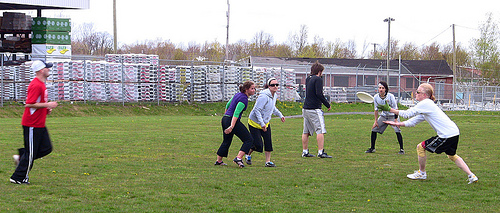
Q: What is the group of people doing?
A: Frisbee.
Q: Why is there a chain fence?
A: To separate the field and building.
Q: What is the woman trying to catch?
A: Frisbee.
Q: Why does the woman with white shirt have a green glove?
A: Protection for hand.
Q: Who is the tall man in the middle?
A: Player.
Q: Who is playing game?
A: Young woman.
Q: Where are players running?
A: Field.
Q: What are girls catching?
A: Frisbee.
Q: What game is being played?
A: Tennis.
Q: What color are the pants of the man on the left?
A: Black.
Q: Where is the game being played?
A: In a field.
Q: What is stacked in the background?
A: Chairs.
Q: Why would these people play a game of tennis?
A: For exercise.